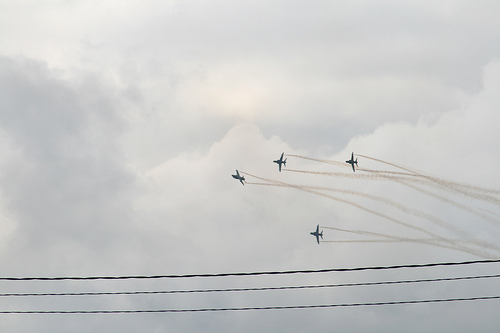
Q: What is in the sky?
A: Planes.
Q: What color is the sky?
A: Blue.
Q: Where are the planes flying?
A: The sky.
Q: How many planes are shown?
A: Four.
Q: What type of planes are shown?
A: Fighter.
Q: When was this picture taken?
A: Daytime.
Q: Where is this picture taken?
A: The sky.